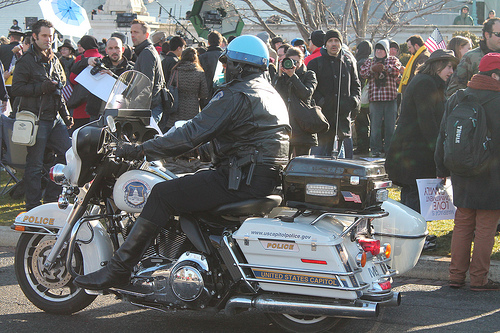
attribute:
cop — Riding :
[67, 32, 294, 289]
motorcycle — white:
[3, 121, 459, 301]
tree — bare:
[297, 0, 398, 52]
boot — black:
[73, 216, 158, 290]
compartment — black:
[277, 153, 384, 209]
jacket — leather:
[132, 73, 293, 173]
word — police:
[21, 215, 55, 227]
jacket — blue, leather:
[145, 82, 311, 189]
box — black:
[277, 152, 393, 214]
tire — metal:
[7, 224, 122, 318]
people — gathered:
[6, 31, 498, 171]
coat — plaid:
[358, 54, 404, 104]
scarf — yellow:
[396, 44, 426, 83]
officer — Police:
[76, 33, 289, 290]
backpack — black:
[434, 94, 495, 174]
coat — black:
[173, 86, 326, 191]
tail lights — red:
[362, 223, 404, 266]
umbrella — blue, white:
[39, 0, 91, 40]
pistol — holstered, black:
[211, 144, 256, 191]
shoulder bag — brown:
[11, 97, 44, 147]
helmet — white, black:
[201, 29, 269, 73]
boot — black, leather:
[68, 216, 162, 291]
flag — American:
[337, 186, 362, 208]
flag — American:
[423, 23, 447, 57]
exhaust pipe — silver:
[229, 290, 396, 313]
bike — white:
[28, 193, 362, 300]